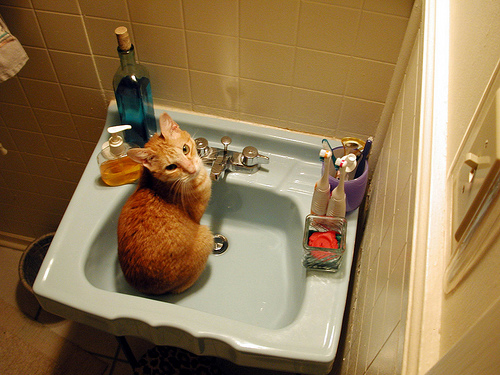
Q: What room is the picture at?
A: It is at the bathroom.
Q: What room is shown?
A: It is a bathroom.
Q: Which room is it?
A: It is a bathroom.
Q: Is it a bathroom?
A: Yes, it is a bathroom.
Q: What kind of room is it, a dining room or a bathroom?
A: It is a bathroom.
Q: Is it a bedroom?
A: No, it is a bathroom.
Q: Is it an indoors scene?
A: Yes, it is indoors.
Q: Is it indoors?
A: Yes, it is indoors.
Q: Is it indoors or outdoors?
A: It is indoors.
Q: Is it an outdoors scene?
A: No, it is indoors.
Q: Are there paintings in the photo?
A: No, there are no paintings.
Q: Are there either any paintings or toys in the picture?
A: No, there are no paintings or toys.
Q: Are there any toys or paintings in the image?
A: No, there are no paintings or toys.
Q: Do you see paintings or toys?
A: No, there are no paintings or toys.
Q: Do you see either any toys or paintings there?
A: No, there are no paintings or toys.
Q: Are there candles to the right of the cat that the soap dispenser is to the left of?
A: Yes, there is a candle to the right of the cat.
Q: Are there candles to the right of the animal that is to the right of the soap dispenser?
A: Yes, there is a candle to the right of the cat.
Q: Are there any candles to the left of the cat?
A: No, the candle is to the right of the cat.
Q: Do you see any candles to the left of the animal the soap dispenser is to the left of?
A: No, the candle is to the right of the cat.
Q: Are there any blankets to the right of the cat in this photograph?
A: No, there is a candle to the right of the cat.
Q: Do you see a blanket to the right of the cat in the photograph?
A: No, there is a candle to the right of the cat.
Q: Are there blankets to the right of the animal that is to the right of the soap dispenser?
A: No, there is a candle to the right of the cat.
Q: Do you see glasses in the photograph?
A: No, there are no glasses.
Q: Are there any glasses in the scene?
A: No, there are no glasses.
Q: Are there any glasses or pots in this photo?
A: No, there are no glasses or pots.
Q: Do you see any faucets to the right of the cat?
A: Yes, there is a faucet to the right of the cat.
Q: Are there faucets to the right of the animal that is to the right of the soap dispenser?
A: Yes, there is a faucet to the right of the cat.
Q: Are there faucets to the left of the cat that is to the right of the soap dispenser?
A: No, the faucet is to the right of the cat.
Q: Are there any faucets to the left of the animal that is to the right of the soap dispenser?
A: No, the faucet is to the right of the cat.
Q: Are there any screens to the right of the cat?
A: No, there is a faucet to the right of the cat.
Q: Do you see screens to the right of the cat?
A: No, there is a faucet to the right of the cat.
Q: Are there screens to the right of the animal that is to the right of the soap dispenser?
A: No, there is a faucet to the right of the cat.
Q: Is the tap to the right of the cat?
A: Yes, the tap is to the right of the cat.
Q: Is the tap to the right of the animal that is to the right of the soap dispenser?
A: Yes, the tap is to the right of the cat.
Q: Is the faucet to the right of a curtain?
A: No, the faucet is to the right of the cat.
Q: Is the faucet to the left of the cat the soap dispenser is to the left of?
A: No, the faucet is to the right of the cat.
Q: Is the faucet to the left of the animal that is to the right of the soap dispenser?
A: No, the faucet is to the right of the cat.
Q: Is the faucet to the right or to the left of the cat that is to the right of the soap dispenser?
A: The faucet is to the right of the cat.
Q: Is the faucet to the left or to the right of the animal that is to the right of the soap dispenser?
A: The faucet is to the right of the cat.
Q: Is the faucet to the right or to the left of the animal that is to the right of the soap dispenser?
A: The faucet is to the right of the cat.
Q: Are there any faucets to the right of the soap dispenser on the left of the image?
A: Yes, there is a faucet to the right of the soap dispenser.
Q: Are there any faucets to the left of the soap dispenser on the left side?
A: No, the faucet is to the right of the soap dispenser.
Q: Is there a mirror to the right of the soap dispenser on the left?
A: No, there is a faucet to the right of the soap dispenser.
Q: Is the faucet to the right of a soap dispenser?
A: Yes, the faucet is to the right of a soap dispenser.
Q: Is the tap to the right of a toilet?
A: No, the tap is to the right of a soap dispenser.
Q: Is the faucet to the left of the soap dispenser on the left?
A: No, the faucet is to the right of the soap dispenser.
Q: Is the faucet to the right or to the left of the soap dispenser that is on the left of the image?
A: The faucet is to the right of the soap dispenser.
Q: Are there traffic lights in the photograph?
A: No, there are no traffic lights.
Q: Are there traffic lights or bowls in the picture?
A: No, there are no traffic lights or bowls.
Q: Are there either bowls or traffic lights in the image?
A: No, there are no traffic lights or bowls.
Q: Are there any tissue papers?
A: No, there are no tissue papers.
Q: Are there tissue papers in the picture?
A: No, there are no tissue papers.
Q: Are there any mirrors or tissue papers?
A: No, there are no tissue papers or mirrors.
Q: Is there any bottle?
A: Yes, there is a bottle.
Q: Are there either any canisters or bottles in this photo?
A: Yes, there is a bottle.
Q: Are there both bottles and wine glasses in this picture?
A: No, there is a bottle but no wine glasses.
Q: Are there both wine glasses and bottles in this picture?
A: No, there is a bottle but no wine glasses.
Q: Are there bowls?
A: No, there are no bowls.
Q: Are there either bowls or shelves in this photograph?
A: No, there are no bowls or shelves.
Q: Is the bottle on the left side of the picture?
A: Yes, the bottle is on the left of the image.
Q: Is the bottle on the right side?
A: No, the bottle is on the left of the image.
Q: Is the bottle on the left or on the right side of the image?
A: The bottle is on the left of the image.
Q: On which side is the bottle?
A: The bottle is on the left of the image.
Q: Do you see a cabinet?
A: No, there are no cabinets.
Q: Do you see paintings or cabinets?
A: No, there are no cabinets or paintings.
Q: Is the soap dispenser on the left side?
A: Yes, the soap dispenser is on the left of the image.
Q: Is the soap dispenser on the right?
A: No, the soap dispenser is on the left of the image.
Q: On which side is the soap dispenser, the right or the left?
A: The soap dispenser is on the left of the image.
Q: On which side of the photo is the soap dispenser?
A: The soap dispenser is on the left of the image.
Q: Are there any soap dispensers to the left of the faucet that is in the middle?
A: Yes, there is a soap dispenser to the left of the tap.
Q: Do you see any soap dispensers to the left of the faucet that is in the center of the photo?
A: Yes, there is a soap dispenser to the left of the tap.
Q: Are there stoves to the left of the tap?
A: No, there is a soap dispenser to the left of the tap.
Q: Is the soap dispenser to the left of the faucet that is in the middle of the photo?
A: Yes, the soap dispenser is to the left of the tap.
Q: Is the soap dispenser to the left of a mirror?
A: No, the soap dispenser is to the left of the tap.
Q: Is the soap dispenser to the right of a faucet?
A: No, the soap dispenser is to the left of a faucet.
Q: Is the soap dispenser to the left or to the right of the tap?
A: The soap dispenser is to the left of the tap.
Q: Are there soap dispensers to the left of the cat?
A: Yes, there is a soap dispenser to the left of the cat.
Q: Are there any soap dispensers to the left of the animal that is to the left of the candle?
A: Yes, there is a soap dispenser to the left of the cat.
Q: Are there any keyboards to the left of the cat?
A: No, there is a soap dispenser to the left of the cat.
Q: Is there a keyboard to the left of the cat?
A: No, there is a soap dispenser to the left of the cat.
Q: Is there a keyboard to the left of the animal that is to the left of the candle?
A: No, there is a soap dispenser to the left of the cat.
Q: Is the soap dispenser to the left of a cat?
A: Yes, the soap dispenser is to the left of a cat.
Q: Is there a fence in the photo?
A: No, there are no fences.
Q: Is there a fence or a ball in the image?
A: No, there are no fences or balls.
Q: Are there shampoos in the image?
A: No, there are no shampoos.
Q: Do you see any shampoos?
A: No, there are no shampoos.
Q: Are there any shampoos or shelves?
A: No, there are no shampoos or shelves.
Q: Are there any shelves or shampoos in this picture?
A: No, there are no shampoos or shelves.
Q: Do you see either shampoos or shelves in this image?
A: No, there are no shampoos or shelves.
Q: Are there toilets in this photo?
A: No, there are no toilets.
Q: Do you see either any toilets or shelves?
A: No, there are no toilets or shelves.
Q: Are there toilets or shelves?
A: No, there are no toilets or shelves.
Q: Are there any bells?
A: No, there are no bells.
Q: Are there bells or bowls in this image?
A: No, there are no bells or bowls.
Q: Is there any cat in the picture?
A: Yes, there is a cat.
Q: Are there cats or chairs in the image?
A: Yes, there is a cat.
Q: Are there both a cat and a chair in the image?
A: No, there is a cat but no chairs.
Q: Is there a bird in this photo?
A: No, there are no birds.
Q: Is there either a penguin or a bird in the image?
A: No, there are no birds or penguins.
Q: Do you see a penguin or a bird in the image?
A: No, there are no birds or penguins.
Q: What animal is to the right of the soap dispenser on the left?
A: The animal is a cat.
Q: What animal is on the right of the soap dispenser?
A: The animal is a cat.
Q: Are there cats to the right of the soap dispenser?
A: Yes, there is a cat to the right of the soap dispenser.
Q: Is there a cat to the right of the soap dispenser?
A: Yes, there is a cat to the right of the soap dispenser.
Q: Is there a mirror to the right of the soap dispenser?
A: No, there is a cat to the right of the soap dispenser.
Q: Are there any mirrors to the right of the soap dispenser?
A: No, there is a cat to the right of the soap dispenser.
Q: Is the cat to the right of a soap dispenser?
A: Yes, the cat is to the right of a soap dispenser.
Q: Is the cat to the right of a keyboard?
A: No, the cat is to the right of a soap dispenser.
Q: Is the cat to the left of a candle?
A: Yes, the cat is to the left of a candle.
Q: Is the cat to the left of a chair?
A: No, the cat is to the left of a candle.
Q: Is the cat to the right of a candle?
A: No, the cat is to the left of a candle.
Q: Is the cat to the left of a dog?
A: No, the cat is to the left of a candle.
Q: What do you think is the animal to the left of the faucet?
A: The animal is a cat.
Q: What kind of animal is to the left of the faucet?
A: The animal is a cat.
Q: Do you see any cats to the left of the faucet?
A: Yes, there is a cat to the left of the faucet.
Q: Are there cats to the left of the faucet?
A: Yes, there is a cat to the left of the faucet.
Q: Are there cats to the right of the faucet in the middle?
A: No, the cat is to the left of the tap.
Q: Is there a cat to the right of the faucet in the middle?
A: No, the cat is to the left of the tap.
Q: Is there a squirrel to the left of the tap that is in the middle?
A: No, there is a cat to the left of the faucet.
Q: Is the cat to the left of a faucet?
A: Yes, the cat is to the left of a faucet.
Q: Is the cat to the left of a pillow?
A: No, the cat is to the left of a faucet.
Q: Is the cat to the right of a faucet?
A: No, the cat is to the left of a faucet.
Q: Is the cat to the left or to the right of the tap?
A: The cat is to the left of the tap.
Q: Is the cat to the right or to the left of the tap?
A: The cat is to the left of the tap.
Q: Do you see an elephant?
A: No, there are no elephants.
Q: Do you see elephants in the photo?
A: No, there are no elephants.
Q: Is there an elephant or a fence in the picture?
A: No, there are no elephants or fences.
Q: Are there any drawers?
A: No, there are no drawers.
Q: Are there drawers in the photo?
A: No, there are no drawers.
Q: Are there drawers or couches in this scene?
A: No, there are no drawers or couches.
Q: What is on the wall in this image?
A: The light switch is on the wall.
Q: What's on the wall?
A: The light switch is on the wall.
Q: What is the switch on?
A: The switch is on the wall.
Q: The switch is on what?
A: The switch is on the wall.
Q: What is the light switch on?
A: The switch is on the wall.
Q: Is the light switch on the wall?
A: Yes, the light switch is on the wall.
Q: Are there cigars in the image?
A: No, there are no cigars.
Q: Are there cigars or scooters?
A: No, there are no cigars or scooters.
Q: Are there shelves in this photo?
A: No, there are no shelves.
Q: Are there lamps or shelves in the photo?
A: No, there are no shelves or lamps.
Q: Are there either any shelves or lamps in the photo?
A: No, there are no shelves or lamps.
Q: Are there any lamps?
A: No, there are no lamps.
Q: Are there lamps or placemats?
A: No, there are no lamps or placemats.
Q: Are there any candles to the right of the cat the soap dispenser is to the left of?
A: Yes, there is a candle to the right of the cat.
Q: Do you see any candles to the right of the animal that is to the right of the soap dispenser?
A: Yes, there is a candle to the right of the cat.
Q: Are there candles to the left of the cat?
A: No, the candle is to the right of the cat.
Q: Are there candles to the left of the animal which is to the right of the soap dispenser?
A: No, the candle is to the right of the cat.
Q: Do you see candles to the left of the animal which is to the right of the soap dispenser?
A: No, the candle is to the right of the cat.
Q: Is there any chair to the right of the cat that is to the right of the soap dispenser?
A: No, there is a candle to the right of the cat.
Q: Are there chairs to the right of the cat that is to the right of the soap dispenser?
A: No, there is a candle to the right of the cat.